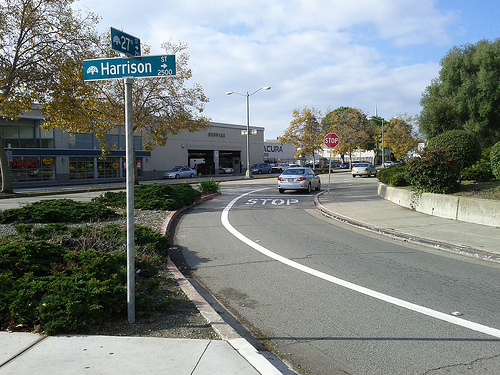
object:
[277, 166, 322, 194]
car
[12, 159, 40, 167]
word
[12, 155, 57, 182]
window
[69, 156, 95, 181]
window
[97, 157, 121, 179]
window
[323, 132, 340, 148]
sign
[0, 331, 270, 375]
sidewalk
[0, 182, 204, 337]
shrubs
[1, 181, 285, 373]
median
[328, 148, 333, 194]
pole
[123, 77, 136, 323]
pole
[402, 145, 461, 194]
bush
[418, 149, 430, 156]
flowers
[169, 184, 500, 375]
road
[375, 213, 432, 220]
ground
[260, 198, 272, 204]
t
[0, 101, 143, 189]
building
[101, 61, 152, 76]
harrison street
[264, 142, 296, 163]
acura building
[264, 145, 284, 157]
dealership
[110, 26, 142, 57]
green streetsign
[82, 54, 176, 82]
green streetsign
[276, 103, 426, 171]
trees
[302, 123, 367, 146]
yellow leaves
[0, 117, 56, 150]
window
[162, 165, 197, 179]
car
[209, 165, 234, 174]
car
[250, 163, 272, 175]
car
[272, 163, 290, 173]
car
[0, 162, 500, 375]
street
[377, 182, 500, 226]
cement wal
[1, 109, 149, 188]
storefront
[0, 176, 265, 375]
corner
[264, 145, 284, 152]
word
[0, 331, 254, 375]
cement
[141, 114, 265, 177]
automotive garage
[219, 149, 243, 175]
bay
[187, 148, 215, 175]
bay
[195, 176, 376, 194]
intersection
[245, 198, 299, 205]
stop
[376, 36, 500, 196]
landscaping